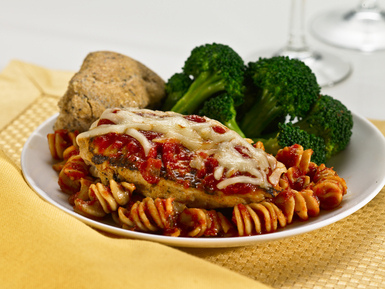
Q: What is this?
A: A meal.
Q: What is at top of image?
A: Broccoli.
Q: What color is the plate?
A: White.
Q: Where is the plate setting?
A: In front of the glass.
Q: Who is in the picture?
A: No one.